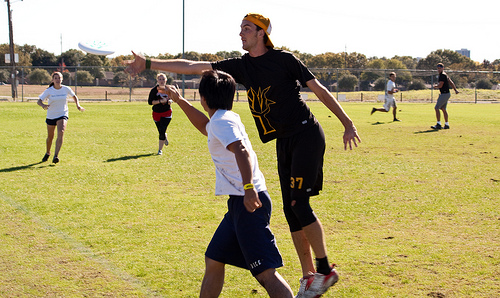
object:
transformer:
[3, 53, 22, 64]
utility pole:
[2, 0, 18, 100]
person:
[426, 64, 459, 132]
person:
[155, 70, 296, 297]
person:
[146, 72, 173, 156]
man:
[123, 10, 360, 297]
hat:
[241, 13, 275, 49]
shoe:
[294, 269, 317, 297]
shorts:
[203, 190, 283, 277]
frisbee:
[76, 43, 114, 57]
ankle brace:
[142, 58, 151, 72]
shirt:
[38, 84, 76, 121]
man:
[368, 71, 402, 122]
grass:
[0, 84, 498, 298]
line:
[0, 191, 158, 297]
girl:
[36, 72, 84, 165]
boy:
[156, 71, 296, 298]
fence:
[0, 65, 499, 104]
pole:
[180, 0, 186, 99]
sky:
[0, 0, 498, 64]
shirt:
[209, 49, 317, 144]